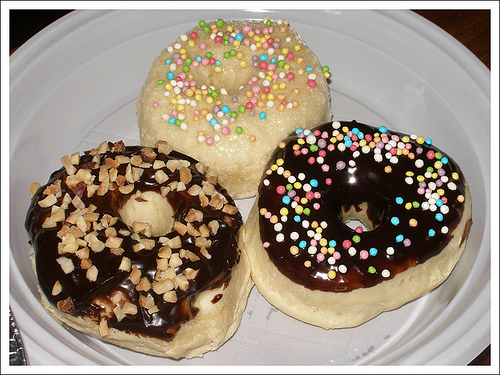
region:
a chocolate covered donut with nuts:
[43, 151, 235, 323]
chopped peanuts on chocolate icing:
[52, 213, 112, 258]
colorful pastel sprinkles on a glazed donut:
[167, 40, 202, 116]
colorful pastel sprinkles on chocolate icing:
[270, 159, 330, 264]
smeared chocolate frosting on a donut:
[70, 280, 121, 306]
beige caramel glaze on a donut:
[153, 109, 177, 132]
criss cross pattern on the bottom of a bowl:
[247, 305, 280, 356]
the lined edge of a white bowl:
[25, 37, 65, 74]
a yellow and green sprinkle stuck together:
[318, 64, 330, 76]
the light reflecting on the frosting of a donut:
[342, 172, 359, 188]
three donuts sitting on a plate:
[23, 15, 482, 364]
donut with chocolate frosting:
[242, 119, 469, 331]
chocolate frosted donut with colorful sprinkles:
[255, 122, 479, 342]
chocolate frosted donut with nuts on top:
[19, 137, 264, 360]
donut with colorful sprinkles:
[131, 18, 331, 196]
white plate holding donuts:
[12, 12, 489, 364]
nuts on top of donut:
[154, 240, 203, 302]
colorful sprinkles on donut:
[307, 136, 384, 159]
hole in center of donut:
[318, 180, 395, 239]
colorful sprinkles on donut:
[205, 103, 236, 133]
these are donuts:
[25, 13, 473, 343]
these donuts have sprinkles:
[142, 15, 472, 290]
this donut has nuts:
[18, 121, 263, 350]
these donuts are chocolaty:
[28, 109, 486, 332]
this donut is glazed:
[138, 21, 339, 170]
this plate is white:
[14, 22, 477, 372]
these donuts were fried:
[58, 47, 385, 318]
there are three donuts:
[31, 17, 483, 362]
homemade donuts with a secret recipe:
[30, 24, 482, 350]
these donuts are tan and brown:
[38, 20, 448, 352]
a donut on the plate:
[239, 117, 474, 332]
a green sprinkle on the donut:
[233, 123, 245, 135]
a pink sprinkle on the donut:
[219, 125, 232, 137]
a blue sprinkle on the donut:
[308, 175, 321, 189]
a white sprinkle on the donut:
[288, 228, 301, 243]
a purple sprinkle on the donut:
[336, 158, 348, 171]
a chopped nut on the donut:
[116, 252, 132, 274]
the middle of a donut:
[111, 185, 179, 243]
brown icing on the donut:
[22, 138, 243, 345]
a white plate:
[8, 10, 490, 366]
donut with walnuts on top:
[14, 116, 270, 365]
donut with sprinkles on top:
[237, 114, 484, 346]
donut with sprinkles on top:
[122, 16, 339, 198]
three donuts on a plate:
[17, 16, 473, 369]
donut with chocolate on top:
[245, 116, 485, 341]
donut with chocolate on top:
[11, 124, 259, 368]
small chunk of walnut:
[149, 278, 180, 298]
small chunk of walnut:
[117, 255, 137, 272]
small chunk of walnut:
[82, 263, 104, 284]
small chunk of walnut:
[47, 278, 64, 298]